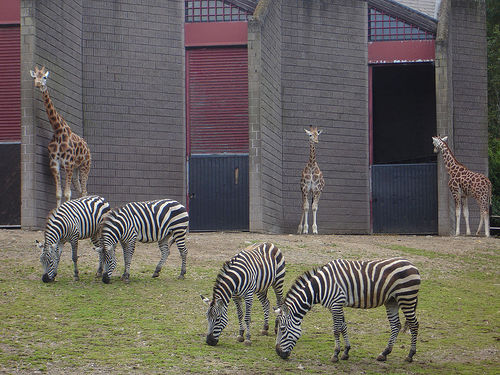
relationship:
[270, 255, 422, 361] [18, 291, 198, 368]
zebra in field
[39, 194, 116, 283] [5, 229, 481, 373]
zebra in field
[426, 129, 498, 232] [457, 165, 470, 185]
giraffe has spots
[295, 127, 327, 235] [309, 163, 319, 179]
giraffe has spots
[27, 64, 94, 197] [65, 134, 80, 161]
giraffe has spots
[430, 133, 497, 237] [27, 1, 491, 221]
giraffe standing against wall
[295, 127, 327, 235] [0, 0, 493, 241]
giraffe standing against wall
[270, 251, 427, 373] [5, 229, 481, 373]
zebra in field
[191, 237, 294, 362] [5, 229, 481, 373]
zebra in field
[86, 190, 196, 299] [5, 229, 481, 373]
zebra in field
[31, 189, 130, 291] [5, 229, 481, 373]
zebra in field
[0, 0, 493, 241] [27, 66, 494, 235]
wall behind giraffes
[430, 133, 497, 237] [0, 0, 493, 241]
giraffe are close to wall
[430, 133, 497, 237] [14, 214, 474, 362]
giraffe in field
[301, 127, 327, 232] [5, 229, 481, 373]
giraffe in field